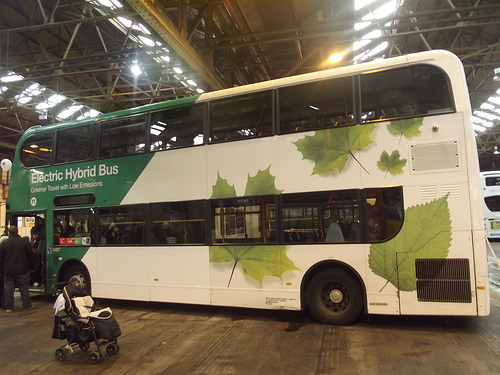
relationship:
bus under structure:
[5, 48, 490, 328] [1, 1, 500, 173]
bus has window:
[5, 48, 490, 328] [16, 130, 56, 173]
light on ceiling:
[130, 61, 145, 79] [2, 0, 499, 169]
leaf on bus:
[367, 192, 451, 293] [5, 48, 490, 328]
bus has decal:
[5, 48, 490, 328] [30, 160, 120, 184]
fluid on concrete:
[283, 315, 309, 333] [3, 290, 500, 375]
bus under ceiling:
[5, 48, 490, 328] [2, 0, 499, 169]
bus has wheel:
[5, 48, 490, 328] [302, 266, 366, 326]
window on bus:
[55, 123, 100, 169] [5, 48, 490, 328]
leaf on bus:
[377, 148, 408, 182] [5, 48, 490, 328]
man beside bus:
[2, 227, 34, 314] [5, 48, 490, 328]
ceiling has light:
[2, 0, 499, 169] [130, 61, 145, 79]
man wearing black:
[2, 227, 34, 314] [2, 235, 35, 279]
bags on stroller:
[50, 313, 72, 342] [51, 280, 120, 364]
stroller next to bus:
[51, 280, 120, 364] [5, 48, 490, 328]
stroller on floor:
[51, 280, 120, 364] [3, 290, 500, 375]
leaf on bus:
[290, 124, 377, 176] [5, 48, 490, 328]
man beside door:
[2, 227, 34, 314] [6, 210, 48, 292]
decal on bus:
[30, 160, 120, 184] [5, 48, 490, 328]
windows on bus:
[19, 62, 457, 172] [5, 48, 490, 328]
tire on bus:
[302, 266, 366, 326] [5, 48, 490, 328]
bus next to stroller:
[5, 48, 490, 328] [51, 280, 120, 364]